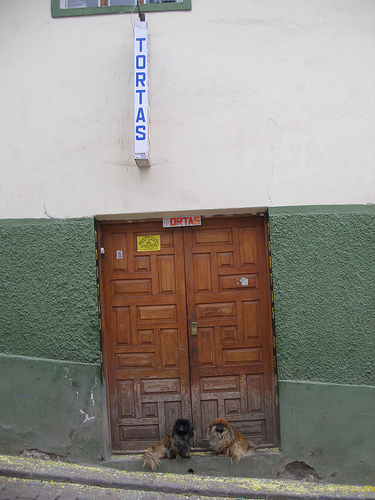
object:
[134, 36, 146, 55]
words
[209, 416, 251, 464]
dog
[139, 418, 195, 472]
dog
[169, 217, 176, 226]
lettering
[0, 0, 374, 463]
wall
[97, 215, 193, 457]
door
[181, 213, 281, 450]
door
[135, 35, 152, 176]
sign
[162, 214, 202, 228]
sign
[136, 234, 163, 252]
sign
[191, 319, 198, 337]
handle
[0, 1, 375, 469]
building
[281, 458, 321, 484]
hole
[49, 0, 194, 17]
window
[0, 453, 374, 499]
street